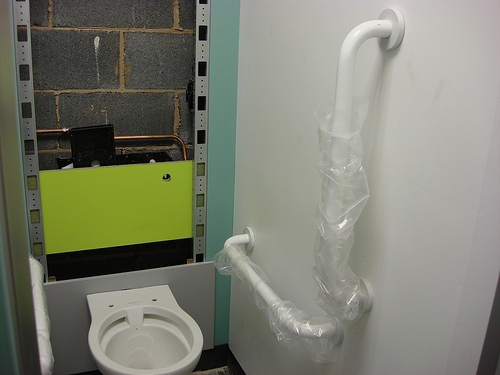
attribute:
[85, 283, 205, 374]
toilet — white, lidless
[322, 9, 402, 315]
bar — standing, white, vertical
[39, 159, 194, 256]
panel — green, bright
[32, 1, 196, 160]
wall — old, brick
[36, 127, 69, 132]
pipe — brass, copper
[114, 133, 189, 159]
pipe — brass, bent, copper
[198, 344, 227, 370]
strip — black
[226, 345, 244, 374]
strip — black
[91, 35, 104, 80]
paint — white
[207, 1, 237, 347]
board — green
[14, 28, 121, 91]
block — cement, gray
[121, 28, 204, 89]
block — cement, gray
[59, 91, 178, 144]
block — cement, gray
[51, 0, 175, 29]
block — cement, gray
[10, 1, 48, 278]
beam — metal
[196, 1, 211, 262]
beam — metal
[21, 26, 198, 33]
grout — brown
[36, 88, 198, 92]
grout — brown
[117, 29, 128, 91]
grout — brown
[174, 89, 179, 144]
grout — brown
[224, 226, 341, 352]
handle — white, horizontal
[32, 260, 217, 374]
panel — gray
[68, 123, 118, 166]
panel — small, black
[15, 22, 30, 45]
cutout — rectangular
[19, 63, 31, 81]
cutout — rectangular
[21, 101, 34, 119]
cutout — rectangular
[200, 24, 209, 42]
cutout — rectangular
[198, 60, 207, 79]
cutout — rectangular